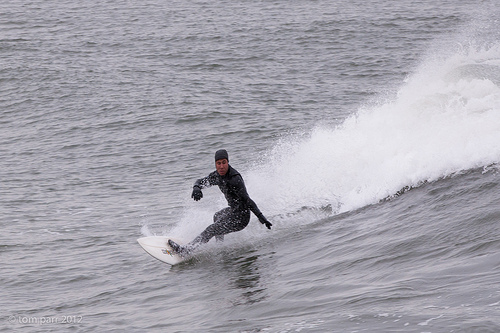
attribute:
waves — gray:
[209, 68, 394, 132]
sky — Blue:
[401, 206, 418, 217]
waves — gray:
[295, 71, 463, 258]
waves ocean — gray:
[355, 99, 463, 196]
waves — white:
[338, 75, 463, 228]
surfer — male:
[132, 147, 273, 265]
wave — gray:
[169, 56, 498, 228]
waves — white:
[323, 85, 445, 191]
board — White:
[134, 234, 182, 271]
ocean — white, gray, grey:
[2, 0, 499, 331]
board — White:
[138, 231, 190, 266]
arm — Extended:
[259, 218, 271, 228]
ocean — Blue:
[25, 18, 491, 331]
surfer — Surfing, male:
[164, 147, 274, 257]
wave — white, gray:
[3, 1, 499, 331]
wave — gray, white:
[185, 11, 498, 259]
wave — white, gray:
[159, 26, 499, 256]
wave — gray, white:
[175, 50, 499, 256]